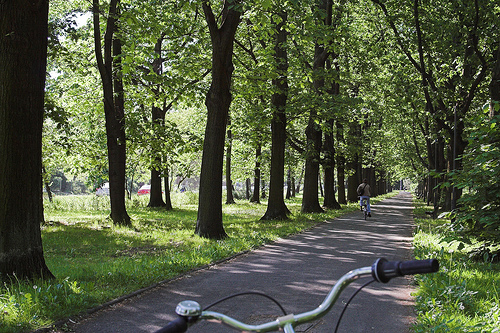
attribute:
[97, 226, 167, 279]
grass — green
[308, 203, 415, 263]
path — riding, grey, clear, close, far, gravel, clean, below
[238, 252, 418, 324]
bike — silver, close, black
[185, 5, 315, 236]
trees — green, tall, black